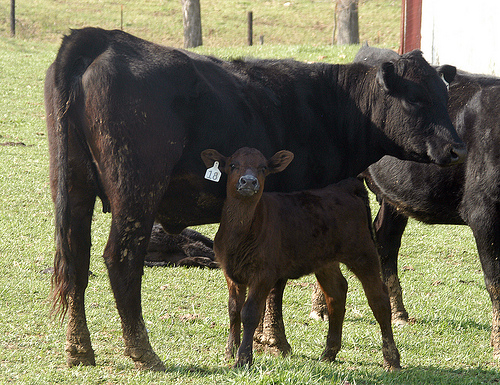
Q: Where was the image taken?
A: It was taken at the pasture.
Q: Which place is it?
A: It is a pasture.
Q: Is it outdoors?
A: Yes, it is outdoors.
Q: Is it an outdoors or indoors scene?
A: It is outdoors.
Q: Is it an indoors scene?
A: No, it is outdoors.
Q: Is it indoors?
A: No, it is outdoors.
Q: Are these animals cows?
A: Yes, all the animals are cows.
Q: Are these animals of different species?
A: No, all the animals are cows.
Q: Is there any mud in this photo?
A: Yes, there is mud.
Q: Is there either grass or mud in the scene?
A: Yes, there is mud.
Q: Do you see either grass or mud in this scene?
A: Yes, there is mud.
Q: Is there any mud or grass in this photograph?
A: Yes, there is mud.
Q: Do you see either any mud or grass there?
A: Yes, there is mud.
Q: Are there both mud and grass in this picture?
A: Yes, there are both mud and grass.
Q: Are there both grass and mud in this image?
A: Yes, there are both mud and grass.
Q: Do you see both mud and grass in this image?
A: Yes, there are both mud and grass.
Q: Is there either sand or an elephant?
A: No, there are no elephants or sand.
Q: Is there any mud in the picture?
A: Yes, there is mud.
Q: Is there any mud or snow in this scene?
A: Yes, there is mud.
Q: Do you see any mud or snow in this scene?
A: Yes, there is mud.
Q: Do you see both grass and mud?
A: Yes, there are both mud and grass.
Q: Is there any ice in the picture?
A: No, there is no ice.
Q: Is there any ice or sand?
A: No, there are no ice or sand.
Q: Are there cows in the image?
A: Yes, there is a cow.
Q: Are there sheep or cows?
A: Yes, there is a cow.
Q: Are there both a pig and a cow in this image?
A: No, there is a cow but no pigs.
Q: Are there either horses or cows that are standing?
A: Yes, the cow is standing.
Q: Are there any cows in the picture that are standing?
A: Yes, there is a cow that is standing.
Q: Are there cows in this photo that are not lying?
A: Yes, there is a cow that is standing.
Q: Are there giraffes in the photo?
A: No, there are no giraffes.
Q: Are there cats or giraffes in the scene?
A: No, there are no giraffes or cats.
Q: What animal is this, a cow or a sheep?
A: This is a cow.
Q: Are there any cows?
A: Yes, there is a cow.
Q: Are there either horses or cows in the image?
A: Yes, there is a cow.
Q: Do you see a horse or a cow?
A: Yes, there is a cow.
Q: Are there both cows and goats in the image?
A: No, there is a cow but no goats.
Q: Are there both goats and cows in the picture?
A: No, there is a cow but no goats.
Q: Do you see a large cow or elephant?
A: Yes, there is a large cow.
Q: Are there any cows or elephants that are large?
A: Yes, the cow is large.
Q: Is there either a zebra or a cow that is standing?
A: Yes, the cow is standing.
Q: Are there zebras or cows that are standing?
A: Yes, the cow is standing.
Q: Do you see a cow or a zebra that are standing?
A: Yes, the cow is standing.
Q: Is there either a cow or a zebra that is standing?
A: Yes, the cow is standing.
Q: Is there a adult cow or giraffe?
A: Yes, there is an adult cow.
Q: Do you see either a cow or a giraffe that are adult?
A: Yes, the cow is adult.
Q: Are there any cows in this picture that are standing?
A: Yes, there is a cow that is standing.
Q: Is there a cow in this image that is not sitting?
A: Yes, there is a cow that is standing.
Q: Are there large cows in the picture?
A: Yes, there is a large cow.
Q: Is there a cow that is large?
A: Yes, there is a cow that is large.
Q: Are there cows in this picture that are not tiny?
A: Yes, there is a large cow.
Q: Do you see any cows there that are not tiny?
A: Yes, there is a large cow.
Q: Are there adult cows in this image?
A: Yes, there is an adult cow.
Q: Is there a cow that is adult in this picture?
A: Yes, there is an adult cow.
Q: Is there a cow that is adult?
A: Yes, there is a cow that is adult.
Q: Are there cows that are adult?
A: Yes, there is a cow that is adult.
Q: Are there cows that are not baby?
A: Yes, there is a adult cow.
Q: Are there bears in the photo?
A: No, there are no bears.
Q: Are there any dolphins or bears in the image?
A: No, there are no bears or dolphins.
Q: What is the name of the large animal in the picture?
A: The animal is a cow.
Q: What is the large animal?
A: The animal is a cow.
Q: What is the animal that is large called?
A: The animal is a cow.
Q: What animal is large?
A: The animal is a cow.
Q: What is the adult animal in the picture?
A: The animal is a cow.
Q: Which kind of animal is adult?
A: The animal is a cow.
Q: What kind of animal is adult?
A: The animal is a cow.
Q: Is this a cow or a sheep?
A: This is a cow.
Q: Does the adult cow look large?
A: Yes, the cow is large.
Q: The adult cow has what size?
A: The cow is large.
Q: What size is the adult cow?
A: The cow is large.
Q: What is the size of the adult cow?
A: The cow is large.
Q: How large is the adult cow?
A: The cow is large.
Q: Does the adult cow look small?
A: No, the cow is large.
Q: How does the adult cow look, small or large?
A: The cow is large.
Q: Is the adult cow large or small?
A: The cow is large.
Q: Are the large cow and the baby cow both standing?
A: Yes, both the cow and the cow are standing.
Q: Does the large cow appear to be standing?
A: Yes, the cow is standing.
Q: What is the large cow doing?
A: The cow is standing.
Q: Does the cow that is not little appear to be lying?
A: No, the cow is standing.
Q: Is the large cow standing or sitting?
A: The cow is standing.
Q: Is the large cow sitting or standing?
A: The cow is standing.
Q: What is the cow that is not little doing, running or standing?
A: The cow is standing.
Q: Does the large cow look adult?
A: Yes, the cow is adult.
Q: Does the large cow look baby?
A: No, the cow is adult.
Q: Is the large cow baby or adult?
A: The cow is adult.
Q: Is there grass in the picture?
A: Yes, there is grass.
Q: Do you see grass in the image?
A: Yes, there is grass.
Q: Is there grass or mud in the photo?
A: Yes, there is grass.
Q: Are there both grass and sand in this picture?
A: No, there is grass but no sand.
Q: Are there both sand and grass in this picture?
A: No, there is grass but no sand.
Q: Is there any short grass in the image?
A: Yes, there is short grass.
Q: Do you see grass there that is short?
A: Yes, there is grass that is short.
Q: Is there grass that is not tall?
A: Yes, there is short grass.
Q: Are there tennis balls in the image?
A: No, there are no tennis balls.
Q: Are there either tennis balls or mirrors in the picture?
A: No, there are no tennis balls or mirrors.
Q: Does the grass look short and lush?
A: Yes, the grass is short and lush.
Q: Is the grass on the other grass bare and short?
A: No, the grass is short but lush.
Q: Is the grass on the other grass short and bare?
A: No, the grass is short but lush.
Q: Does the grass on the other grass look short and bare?
A: No, the grass is short but lush.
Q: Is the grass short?
A: Yes, the grass is short.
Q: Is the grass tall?
A: No, the grass is short.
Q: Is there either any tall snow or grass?
A: No, there is grass but it is short.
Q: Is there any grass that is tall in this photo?
A: No, there is grass but it is short.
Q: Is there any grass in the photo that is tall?
A: No, there is grass but it is short.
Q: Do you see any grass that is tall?
A: No, there is grass but it is short.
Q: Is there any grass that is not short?
A: No, there is grass but it is short.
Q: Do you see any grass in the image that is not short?
A: No, there is grass but it is short.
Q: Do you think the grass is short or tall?
A: The grass is short.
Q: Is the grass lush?
A: Yes, the grass is lush.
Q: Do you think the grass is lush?
A: Yes, the grass is lush.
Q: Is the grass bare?
A: No, the grass is lush.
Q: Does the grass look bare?
A: No, the grass is lush.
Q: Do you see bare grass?
A: No, there is grass but it is lush.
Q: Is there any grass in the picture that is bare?
A: No, there is grass but it is lush.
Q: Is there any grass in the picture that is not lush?
A: No, there is grass but it is lush.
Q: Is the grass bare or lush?
A: The grass is lush.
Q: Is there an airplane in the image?
A: No, there are no airplanes.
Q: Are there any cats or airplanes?
A: No, there are no airplanes or cats.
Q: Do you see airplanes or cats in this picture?
A: No, there are no airplanes or cats.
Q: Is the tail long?
A: Yes, the tail is long.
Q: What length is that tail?
A: The tail is long.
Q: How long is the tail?
A: The tail is long.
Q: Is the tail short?
A: No, the tail is long.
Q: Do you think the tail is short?
A: No, the tail is long.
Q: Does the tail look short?
A: No, the tail is long.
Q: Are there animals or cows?
A: Yes, there is a cow.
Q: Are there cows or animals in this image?
A: Yes, there is a cow.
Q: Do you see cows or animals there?
A: Yes, there is a cow.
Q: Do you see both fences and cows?
A: Yes, there are both a cow and a fence.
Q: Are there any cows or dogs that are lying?
A: Yes, the cow is lying.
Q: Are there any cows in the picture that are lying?
A: Yes, there is a cow that is lying.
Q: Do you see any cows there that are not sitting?
A: Yes, there is a cow that is lying .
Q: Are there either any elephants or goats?
A: No, there are no elephants or goats.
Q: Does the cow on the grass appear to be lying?
A: Yes, the cow is lying.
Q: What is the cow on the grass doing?
A: The cow is lying.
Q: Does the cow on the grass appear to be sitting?
A: No, the cow is lying.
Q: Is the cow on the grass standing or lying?
A: The cow is lying.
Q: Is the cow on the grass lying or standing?
A: The cow is lying.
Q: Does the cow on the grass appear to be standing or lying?
A: The cow is lying.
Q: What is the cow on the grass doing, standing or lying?
A: The cow is lying.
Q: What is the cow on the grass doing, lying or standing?
A: The cow is lying.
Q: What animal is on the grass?
A: The animal is a cow.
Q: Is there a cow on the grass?
A: Yes, there is a cow on the grass.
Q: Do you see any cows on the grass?
A: Yes, there is a cow on the grass.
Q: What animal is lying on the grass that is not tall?
A: The cow is lying on the grass.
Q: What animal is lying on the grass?
A: The cow is lying on the grass.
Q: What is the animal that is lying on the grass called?
A: The animal is a cow.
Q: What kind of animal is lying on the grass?
A: The animal is a cow.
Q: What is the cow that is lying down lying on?
A: The cow is lying on the grass.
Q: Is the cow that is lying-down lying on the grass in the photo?
A: Yes, the cow is lying on the grass.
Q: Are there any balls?
A: No, there are no balls.